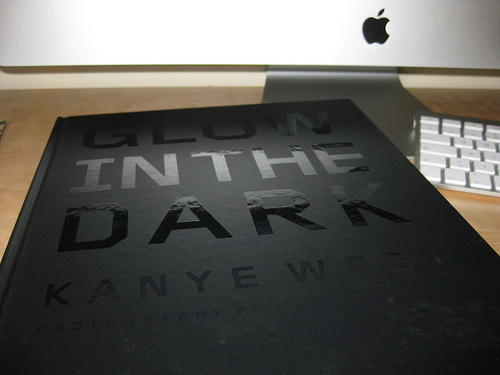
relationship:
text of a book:
[67, 133, 371, 200] [10, 95, 496, 372]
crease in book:
[10, 109, 69, 260] [10, 95, 496, 372]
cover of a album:
[55, 103, 458, 373] [0, 83, 485, 373]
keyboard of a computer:
[412, 105, 500, 193] [2, 0, 479, 164]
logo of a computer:
[360, 5, 392, 49] [0, 2, 407, 102]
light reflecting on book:
[88, 150, 212, 200] [10, 95, 496, 372]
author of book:
[35, 228, 448, 311] [10, 95, 496, 372]